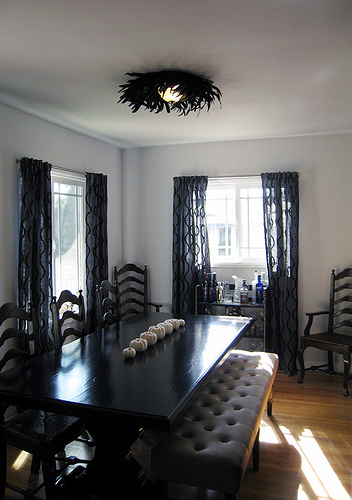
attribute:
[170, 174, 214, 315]
curtain panel — decorative, black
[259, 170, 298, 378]
curtain panel — black, decorative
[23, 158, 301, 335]
curtain panel —  decorative black 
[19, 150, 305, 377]
curtain panel —  decorative black 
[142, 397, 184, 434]
table —  Edge 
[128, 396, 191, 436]
table —  Edge 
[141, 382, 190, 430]
table —  Edge 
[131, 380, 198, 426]
table —  Edge 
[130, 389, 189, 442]
table —  Edge 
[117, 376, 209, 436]
table —  Edge 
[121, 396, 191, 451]
table —  Edge 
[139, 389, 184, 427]
table —  Edge 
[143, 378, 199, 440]
table —  Edge 